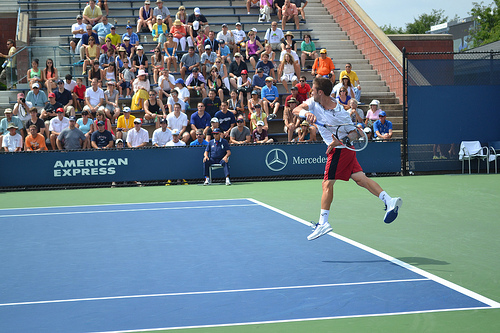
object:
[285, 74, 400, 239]
man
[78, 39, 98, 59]
spectators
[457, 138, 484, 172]
chair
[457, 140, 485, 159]
towel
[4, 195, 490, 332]
tennis court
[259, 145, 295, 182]
emblem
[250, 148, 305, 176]
sign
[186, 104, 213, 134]
spectator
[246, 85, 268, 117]
spectator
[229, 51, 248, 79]
spectator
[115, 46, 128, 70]
spectator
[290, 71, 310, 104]
spectator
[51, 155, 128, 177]
american express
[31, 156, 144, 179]
sign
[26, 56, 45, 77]
spectators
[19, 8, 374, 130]
crowd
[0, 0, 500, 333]
tennis game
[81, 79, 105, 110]
spectators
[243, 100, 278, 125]
spectators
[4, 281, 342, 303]
line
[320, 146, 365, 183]
shorts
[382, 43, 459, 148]
wall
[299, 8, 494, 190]
building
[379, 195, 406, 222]
tennis shoe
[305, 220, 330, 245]
tennis shoe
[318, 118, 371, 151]
racket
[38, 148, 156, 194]
sponsor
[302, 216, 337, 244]
shoe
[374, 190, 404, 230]
shoe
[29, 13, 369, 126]
stand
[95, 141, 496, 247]
edging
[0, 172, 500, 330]
court